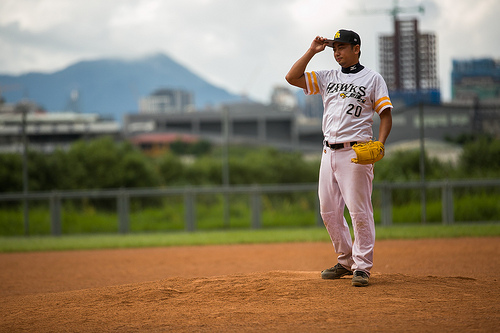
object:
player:
[285, 29, 394, 287]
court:
[1, 235, 498, 332]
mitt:
[351, 139, 385, 165]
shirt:
[302, 62, 393, 144]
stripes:
[305, 71, 320, 96]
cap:
[323, 29, 361, 47]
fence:
[0, 183, 318, 238]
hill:
[0, 51, 250, 120]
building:
[139, 86, 195, 115]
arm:
[285, 50, 329, 91]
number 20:
[346, 104, 362, 118]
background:
[0, 13, 295, 69]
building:
[376, 2, 440, 99]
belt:
[324, 140, 357, 150]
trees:
[0, 136, 303, 214]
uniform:
[303, 67, 393, 278]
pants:
[317, 145, 376, 278]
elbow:
[285, 73, 307, 84]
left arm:
[373, 73, 393, 145]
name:
[326, 83, 367, 96]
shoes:
[320, 262, 369, 286]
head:
[332, 41, 361, 65]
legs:
[317, 174, 373, 287]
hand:
[310, 36, 329, 54]